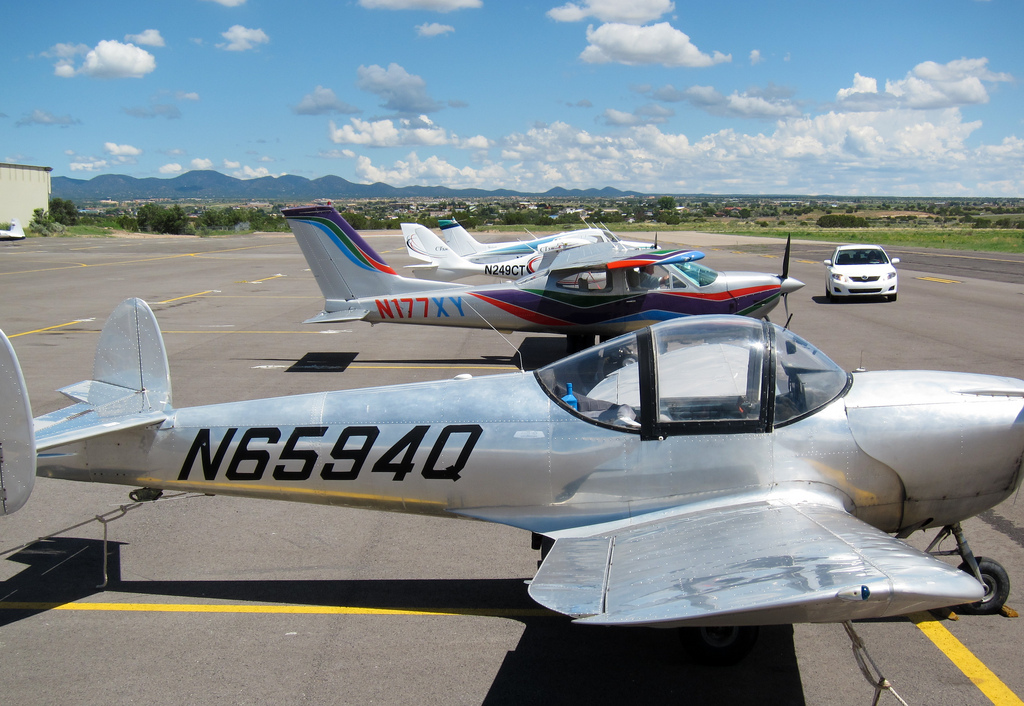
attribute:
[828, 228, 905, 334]
car — small, white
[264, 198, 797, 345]
airplane — colorful, small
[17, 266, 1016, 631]
airplane — silver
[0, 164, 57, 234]
building — white